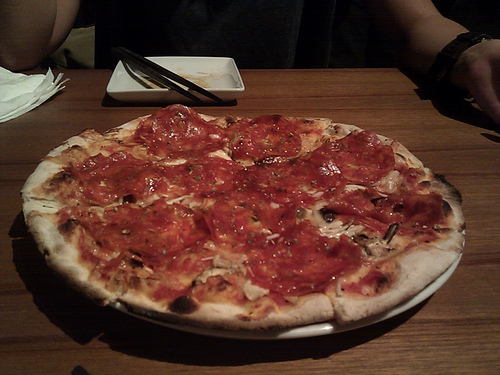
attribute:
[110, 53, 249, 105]
bowl — white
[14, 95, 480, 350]
plate — white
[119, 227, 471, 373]
plate — white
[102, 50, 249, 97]
plate — white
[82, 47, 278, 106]
plate — tiny, white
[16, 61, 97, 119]
napkin — white